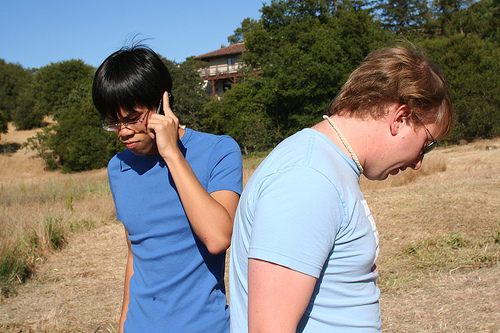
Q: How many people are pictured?
A: Two.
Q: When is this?
A: Daytime.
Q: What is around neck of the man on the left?
A: A necklace.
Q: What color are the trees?
A: Green.